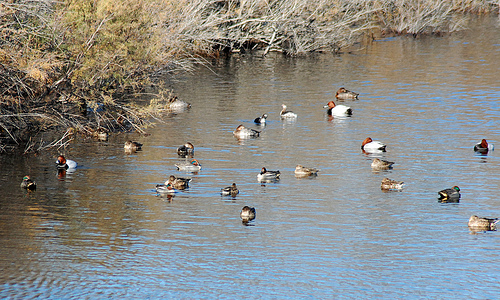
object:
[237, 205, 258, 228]
ducks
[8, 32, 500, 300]
surface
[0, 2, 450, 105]
bush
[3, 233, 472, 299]
water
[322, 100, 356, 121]
duck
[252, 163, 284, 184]
duck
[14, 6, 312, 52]
twig branch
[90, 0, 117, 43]
trees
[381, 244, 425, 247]
ripples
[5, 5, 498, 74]
bank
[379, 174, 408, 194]
duck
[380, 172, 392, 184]
brown head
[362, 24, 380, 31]
branches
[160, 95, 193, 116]
duck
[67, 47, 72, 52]
leaves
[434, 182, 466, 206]
duck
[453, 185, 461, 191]
green head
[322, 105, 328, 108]
beak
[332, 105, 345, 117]
white part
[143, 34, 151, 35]
leaves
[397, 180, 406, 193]
feather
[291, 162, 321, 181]
duck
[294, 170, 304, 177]
chest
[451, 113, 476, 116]
waves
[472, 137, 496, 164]
duck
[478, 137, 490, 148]
red part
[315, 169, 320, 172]
tail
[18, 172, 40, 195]
duck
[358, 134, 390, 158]
duck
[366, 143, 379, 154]
white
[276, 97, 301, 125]
duck